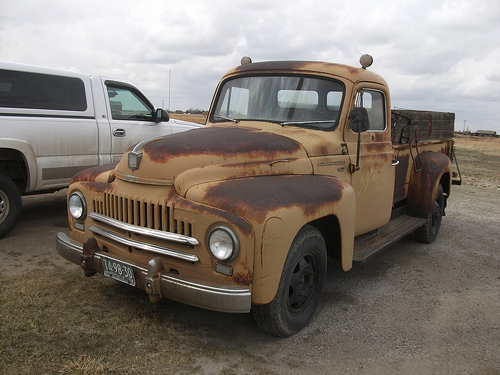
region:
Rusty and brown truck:
[53, 40, 462, 345]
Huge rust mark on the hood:
[130, 120, 307, 160]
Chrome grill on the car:
[82, 214, 199, 266]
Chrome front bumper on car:
[51, 233, 259, 318]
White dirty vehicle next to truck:
[0, 58, 209, 246]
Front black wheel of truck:
[261, 225, 330, 337]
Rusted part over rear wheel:
[411, 146, 452, 220]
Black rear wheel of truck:
[416, 176, 454, 245]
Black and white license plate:
[96, 253, 136, 290]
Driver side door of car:
[345, 75, 398, 243]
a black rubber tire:
[268, 230, 338, 333]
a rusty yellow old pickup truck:
[58, 51, 465, 338]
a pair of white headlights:
[206, 226, 238, 263]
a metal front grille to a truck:
[86, 213, 201, 262]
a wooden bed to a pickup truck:
[394, 107, 456, 139]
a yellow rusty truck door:
[341, 85, 397, 236]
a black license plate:
[101, 256, 133, 284]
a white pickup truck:
[1, 73, 211, 193]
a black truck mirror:
[347, 106, 370, 173]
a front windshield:
[213, 70, 340, 130]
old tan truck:
[60, 51, 484, 316]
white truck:
[2, 61, 167, 158]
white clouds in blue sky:
[431, 26, 478, 76]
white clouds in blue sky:
[427, 66, 464, 104]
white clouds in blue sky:
[342, 8, 402, 18]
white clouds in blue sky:
[400, 15, 427, 35]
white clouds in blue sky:
[135, 21, 176, 53]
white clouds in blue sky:
[54, 12, 151, 42]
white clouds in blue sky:
[157, 13, 204, 60]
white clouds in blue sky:
[32, 23, 113, 57]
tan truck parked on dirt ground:
[42, 43, 470, 343]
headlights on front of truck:
[58, 182, 245, 268]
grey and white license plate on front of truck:
[92, 248, 140, 293]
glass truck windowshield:
[205, 64, 346, 149]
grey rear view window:
[347, 103, 372, 137]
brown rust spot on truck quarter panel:
[202, 165, 364, 225]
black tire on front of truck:
[247, 225, 331, 348]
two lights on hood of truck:
[232, 44, 377, 80]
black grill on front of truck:
[80, 181, 200, 243]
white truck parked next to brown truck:
[1, 54, 208, 253]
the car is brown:
[62, 17, 474, 345]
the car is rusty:
[50, 17, 461, 339]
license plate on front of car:
[96, 255, 146, 297]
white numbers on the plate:
[96, 254, 138, 289]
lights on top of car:
[228, 43, 385, 90]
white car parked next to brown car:
[2, 48, 214, 256]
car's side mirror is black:
[343, 97, 384, 173]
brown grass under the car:
[4, 254, 264, 371]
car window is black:
[0, 63, 93, 119]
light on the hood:
[123, 148, 144, 172]